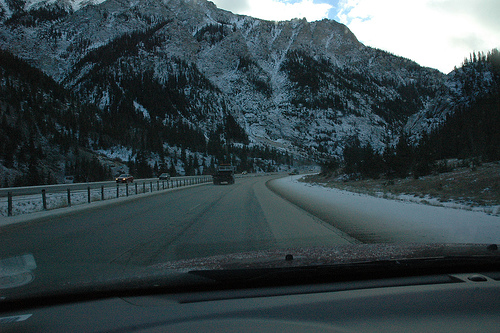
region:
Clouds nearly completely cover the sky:
[209, 0, 493, 68]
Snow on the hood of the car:
[163, 245, 419, 267]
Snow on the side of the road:
[285, 161, 497, 246]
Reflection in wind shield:
[0, 252, 44, 285]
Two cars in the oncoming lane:
[108, 164, 172, 189]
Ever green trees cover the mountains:
[6, 3, 497, 196]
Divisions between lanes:
[9, 175, 224, 212]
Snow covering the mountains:
[1, 7, 498, 149]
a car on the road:
[191, 151, 262, 199]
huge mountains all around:
[0, 3, 497, 160]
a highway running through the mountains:
[4, 47, 484, 320]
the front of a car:
[5, 230, 492, 329]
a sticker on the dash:
[0, 308, 90, 326]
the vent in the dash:
[108, 270, 495, 328]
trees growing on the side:
[292, 121, 482, 186]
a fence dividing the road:
[0, 156, 199, 252]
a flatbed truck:
[211, 157, 241, 187]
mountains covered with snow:
[1, 5, 491, 169]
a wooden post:
[34, 179, 49, 211]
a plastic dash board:
[7, 245, 498, 331]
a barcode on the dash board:
[1, 312, 35, 325]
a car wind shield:
[1, 2, 485, 295]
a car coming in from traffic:
[158, 166, 172, 182]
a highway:
[1, 164, 348, 289]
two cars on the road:
[103, 160, 182, 208]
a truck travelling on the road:
[188, 151, 265, 211]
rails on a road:
[15, 167, 92, 269]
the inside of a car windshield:
[16, 193, 489, 328]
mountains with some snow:
[196, 6, 493, 148]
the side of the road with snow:
[276, 175, 459, 225]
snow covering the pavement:
[294, 179, 478, 205]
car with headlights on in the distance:
[112, 170, 136, 194]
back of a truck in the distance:
[197, 152, 245, 242]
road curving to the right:
[211, 11, 361, 222]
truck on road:
[206, 158, 243, 190]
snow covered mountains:
[7, 0, 497, 167]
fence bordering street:
[4, 170, 225, 222]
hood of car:
[16, 226, 492, 330]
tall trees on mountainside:
[452, 36, 494, 90]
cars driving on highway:
[106, 163, 173, 188]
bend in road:
[1, 160, 351, 280]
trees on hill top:
[3, 48, 281, 180]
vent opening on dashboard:
[172, 273, 472, 315]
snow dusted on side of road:
[269, 172, 497, 243]